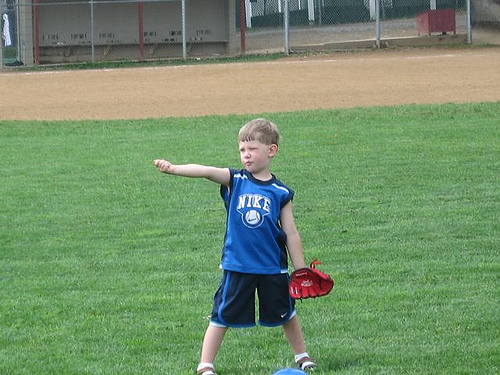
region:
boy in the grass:
[113, 71, 355, 363]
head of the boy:
[215, 100, 272, 177]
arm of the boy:
[137, 146, 234, 188]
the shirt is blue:
[224, 244, 271, 264]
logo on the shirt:
[212, 188, 269, 239]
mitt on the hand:
[294, 249, 339, 295]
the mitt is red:
[302, 276, 319, 291]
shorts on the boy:
[185, 274, 302, 328]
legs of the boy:
[165, 324, 328, 344]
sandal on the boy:
[288, 344, 330, 374]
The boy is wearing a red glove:
[290, 266, 332, 298]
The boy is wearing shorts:
[211, 270, 296, 327]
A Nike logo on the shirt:
[237, 188, 272, 225]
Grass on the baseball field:
[0, 100, 497, 374]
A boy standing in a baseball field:
[154, 118, 333, 373]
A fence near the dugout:
[0, 0, 472, 65]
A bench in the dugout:
[37, 39, 226, 57]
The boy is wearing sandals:
[292, 352, 317, 371]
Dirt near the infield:
[0, 46, 498, 121]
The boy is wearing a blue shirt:
[221, 172, 292, 274]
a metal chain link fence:
[15, 0, 483, 61]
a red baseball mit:
[288, 262, 335, 302]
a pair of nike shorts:
[207, 270, 302, 331]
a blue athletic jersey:
[217, 165, 295, 276]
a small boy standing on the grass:
[148, 116, 335, 373]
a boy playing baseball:
[153, 113, 334, 370]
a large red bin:
[413, 8, 462, 35]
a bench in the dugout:
[35, 34, 231, 56]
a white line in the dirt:
[281, 53, 458, 64]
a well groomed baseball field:
[37, 53, 482, 353]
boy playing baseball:
[145, 113, 322, 373]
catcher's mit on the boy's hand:
[283, 254, 339, 298]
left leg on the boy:
[289, 349, 319, 373]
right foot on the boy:
[195, 358, 218, 373]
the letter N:
[236, 191, 250, 210]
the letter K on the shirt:
[250, 193, 264, 210]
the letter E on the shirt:
[261, 195, 273, 210]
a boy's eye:
[249, 143, 256, 153]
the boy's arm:
[149, 158, 229, 183]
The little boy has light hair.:
[227, 108, 312, 150]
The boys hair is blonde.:
[238, 113, 298, 157]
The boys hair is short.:
[223, 109, 290, 153]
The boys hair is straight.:
[231, 101, 286, 161]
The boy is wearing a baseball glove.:
[276, 245, 352, 298]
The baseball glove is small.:
[286, 245, 368, 322]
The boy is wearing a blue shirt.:
[206, 158, 296, 273]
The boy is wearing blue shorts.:
[199, 258, 321, 342]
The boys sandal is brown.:
[281, 345, 323, 372]